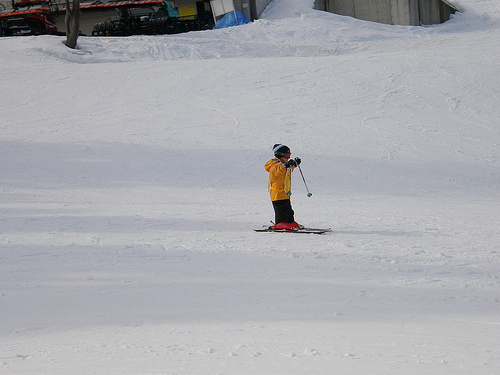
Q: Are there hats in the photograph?
A: Yes, there is a hat.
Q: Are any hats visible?
A: Yes, there is a hat.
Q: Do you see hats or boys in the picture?
A: Yes, there is a hat.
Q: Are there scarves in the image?
A: No, there are no scarves.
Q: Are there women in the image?
A: No, there are no women.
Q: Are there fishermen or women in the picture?
A: No, there are no women or fishermen.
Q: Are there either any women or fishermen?
A: No, there are no women or fishermen.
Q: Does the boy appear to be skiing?
A: Yes, the boy is skiing.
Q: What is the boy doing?
A: The boy is skiing.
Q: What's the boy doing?
A: The boy is skiing.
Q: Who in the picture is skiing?
A: The boy is skiing.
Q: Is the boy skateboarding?
A: No, the boy is skiing.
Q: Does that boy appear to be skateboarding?
A: No, the boy is skiing.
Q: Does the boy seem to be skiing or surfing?
A: The boy is skiing.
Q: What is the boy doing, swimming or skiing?
A: The boy is skiing.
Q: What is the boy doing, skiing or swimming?
A: The boy is skiing.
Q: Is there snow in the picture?
A: Yes, there is snow.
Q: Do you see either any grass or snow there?
A: Yes, there is snow.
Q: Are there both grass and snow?
A: No, there is snow but no grass.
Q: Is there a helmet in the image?
A: No, there are no helmets.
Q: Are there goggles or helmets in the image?
A: No, there are no helmets or goggles.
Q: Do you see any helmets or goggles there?
A: No, there are no helmets or goggles.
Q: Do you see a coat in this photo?
A: Yes, there is a coat.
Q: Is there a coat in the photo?
A: Yes, there is a coat.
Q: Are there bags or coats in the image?
A: Yes, there is a coat.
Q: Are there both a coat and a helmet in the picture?
A: No, there is a coat but no helmets.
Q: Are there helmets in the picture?
A: No, there are no helmets.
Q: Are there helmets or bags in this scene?
A: No, there are no helmets or bags.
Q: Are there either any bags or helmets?
A: No, there are no helmets or bags.